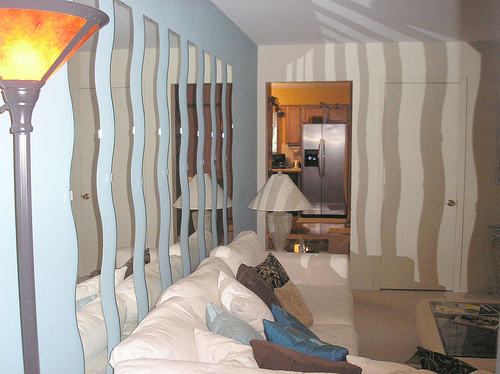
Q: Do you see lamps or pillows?
A: Yes, there is a pillow.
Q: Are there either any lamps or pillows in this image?
A: Yes, there is a pillow.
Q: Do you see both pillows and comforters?
A: No, there is a pillow but no comforters.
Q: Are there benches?
A: No, there are no benches.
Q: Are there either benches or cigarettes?
A: No, there are no benches or cigarettes.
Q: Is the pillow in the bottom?
A: Yes, the pillow is in the bottom of the image.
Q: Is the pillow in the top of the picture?
A: No, the pillow is in the bottom of the image.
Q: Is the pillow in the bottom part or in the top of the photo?
A: The pillow is in the bottom of the image.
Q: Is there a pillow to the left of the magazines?
A: Yes, there is a pillow to the left of the magazines.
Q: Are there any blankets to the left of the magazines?
A: No, there is a pillow to the left of the magazines.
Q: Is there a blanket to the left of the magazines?
A: No, there is a pillow to the left of the magazines.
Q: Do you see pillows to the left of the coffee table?
A: Yes, there is a pillow to the left of the coffee table.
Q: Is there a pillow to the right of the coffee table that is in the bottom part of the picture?
A: No, the pillow is to the left of the coffee table.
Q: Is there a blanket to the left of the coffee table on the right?
A: No, there is a pillow to the left of the coffee table.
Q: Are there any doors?
A: Yes, there is a door.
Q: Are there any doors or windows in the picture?
A: Yes, there is a door.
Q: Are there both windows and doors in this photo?
A: No, there is a door but no windows.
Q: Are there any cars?
A: No, there are no cars.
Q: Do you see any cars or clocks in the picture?
A: No, there are no cars or clocks.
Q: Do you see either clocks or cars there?
A: No, there are no cars or clocks.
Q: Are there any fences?
A: No, there are no fences.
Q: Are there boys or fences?
A: No, there are no fences or boys.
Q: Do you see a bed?
A: No, there are no beds.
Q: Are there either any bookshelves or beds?
A: No, there are no beds or bookshelves.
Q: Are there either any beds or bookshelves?
A: No, there are no beds or bookshelves.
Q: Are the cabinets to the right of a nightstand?
A: No, the cabinets are to the right of a mirror.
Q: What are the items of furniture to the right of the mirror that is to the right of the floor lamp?
A: The pieces of furniture are cabinets.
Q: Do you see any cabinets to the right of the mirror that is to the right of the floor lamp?
A: Yes, there are cabinets to the right of the mirror.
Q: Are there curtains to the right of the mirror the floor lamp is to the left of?
A: No, there are cabinets to the right of the mirror.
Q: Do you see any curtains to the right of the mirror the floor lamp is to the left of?
A: No, there are cabinets to the right of the mirror.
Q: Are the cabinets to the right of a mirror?
A: Yes, the cabinets are to the right of a mirror.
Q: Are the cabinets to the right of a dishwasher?
A: No, the cabinets are to the right of a mirror.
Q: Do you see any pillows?
A: Yes, there is a pillow.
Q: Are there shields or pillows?
A: Yes, there is a pillow.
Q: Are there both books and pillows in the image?
A: No, there is a pillow but no books.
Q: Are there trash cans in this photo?
A: No, there are no trash cans.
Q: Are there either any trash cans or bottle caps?
A: No, there are no trash cans or bottle caps.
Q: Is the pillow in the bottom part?
A: Yes, the pillow is in the bottom of the image.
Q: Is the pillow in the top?
A: No, the pillow is in the bottom of the image.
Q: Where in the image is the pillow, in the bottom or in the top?
A: The pillow is in the bottom of the image.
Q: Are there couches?
A: Yes, there is a couch.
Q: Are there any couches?
A: Yes, there is a couch.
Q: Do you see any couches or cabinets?
A: Yes, there is a couch.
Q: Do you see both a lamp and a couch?
A: Yes, there are both a couch and a lamp.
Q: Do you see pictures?
A: No, there are no pictures.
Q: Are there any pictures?
A: No, there are no pictures.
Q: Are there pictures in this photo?
A: No, there are no pictures.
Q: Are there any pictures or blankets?
A: No, there are no pictures or blankets.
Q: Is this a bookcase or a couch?
A: This is a couch.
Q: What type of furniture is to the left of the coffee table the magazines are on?
A: The piece of furniture is a couch.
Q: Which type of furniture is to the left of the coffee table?
A: The piece of furniture is a couch.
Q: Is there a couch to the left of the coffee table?
A: Yes, there is a couch to the left of the coffee table.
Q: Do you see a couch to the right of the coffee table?
A: No, the couch is to the left of the coffee table.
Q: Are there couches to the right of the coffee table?
A: No, the couch is to the left of the coffee table.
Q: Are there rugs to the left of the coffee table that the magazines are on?
A: No, there is a couch to the left of the coffee table.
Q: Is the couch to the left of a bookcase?
A: No, the couch is to the left of the coffee table.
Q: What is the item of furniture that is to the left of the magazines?
A: The piece of furniture is a couch.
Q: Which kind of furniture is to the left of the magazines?
A: The piece of furniture is a couch.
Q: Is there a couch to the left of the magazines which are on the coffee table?
A: Yes, there is a couch to the left of the magazines.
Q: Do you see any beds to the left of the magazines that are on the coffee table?
A: No, there is a couch to the left of the magazines.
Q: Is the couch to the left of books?
A: No, the couch is to the left of the magazines.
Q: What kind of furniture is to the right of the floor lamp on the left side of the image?
A: The piece of furniture is a couch.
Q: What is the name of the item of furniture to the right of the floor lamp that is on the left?
A: The piece of furniture is a couch.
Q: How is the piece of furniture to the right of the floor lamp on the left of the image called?
A: The piece of furniture is a couch.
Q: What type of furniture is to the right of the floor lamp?
A: The piece of furniture is a couch.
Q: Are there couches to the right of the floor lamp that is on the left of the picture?
A: Yes, there is a couch to the right of the floor lamp.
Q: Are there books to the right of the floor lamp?
A: No, there is a couch to the right of the floor lamp.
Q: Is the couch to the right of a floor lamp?
A: Yes, the couch is to the right of a floor lamp.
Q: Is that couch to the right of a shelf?
A: No, the couch is to the right of a floor lamp.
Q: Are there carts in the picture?
A: No, there are no carts.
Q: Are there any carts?
A: No, there are no carts.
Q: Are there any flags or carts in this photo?
A: No, there are no carts or flags.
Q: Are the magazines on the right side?
A: Yes, the magazines are on the right of the image.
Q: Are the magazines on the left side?
A: No, the magazines are on the right of the image.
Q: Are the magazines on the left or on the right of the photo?
A: The magazines are on the right of the image.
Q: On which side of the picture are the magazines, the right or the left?
A: The magazines are on the right of the image.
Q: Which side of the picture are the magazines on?
A: The magazines are on the right of the image.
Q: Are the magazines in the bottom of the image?
A: Yes, the magazines are in the bottom of the image.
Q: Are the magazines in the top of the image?
A: No, the magazines are in the bottom of the image.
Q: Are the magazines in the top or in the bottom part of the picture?
A: The magazines are in the bottom of the image.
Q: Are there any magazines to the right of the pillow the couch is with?
A: Yes, there are magazines to the right of the pillow.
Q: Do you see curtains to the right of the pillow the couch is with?
A: No, there are magazines to the right of the pillow.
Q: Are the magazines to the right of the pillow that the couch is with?
A: Yes, the magazines are to the right of the pillow.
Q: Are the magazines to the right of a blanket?
A: No, the magazines are to the right of the pillow.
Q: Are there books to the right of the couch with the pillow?
A: No, there are magazines to the right of the couch.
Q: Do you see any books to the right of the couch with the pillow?
A: No, there are magazines to the right of the couch.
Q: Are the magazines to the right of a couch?
A: Yes, the magazines are to the right of a couch.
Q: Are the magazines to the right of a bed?
A: No, the magazines are to the right of a couch.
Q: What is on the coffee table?
A: The magazines are on the coffee table.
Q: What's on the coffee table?
A: The magazines are on the coffee table.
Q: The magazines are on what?
A: The magazines are on the coffee table.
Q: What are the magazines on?
A: The magazines are on the coffee table.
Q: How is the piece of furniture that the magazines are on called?
A: The piece of furniture is a coffee table.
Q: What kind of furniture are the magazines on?
A: The magazines are on the coffee table.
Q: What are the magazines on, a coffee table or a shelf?
A: The magazines are on a coffee table.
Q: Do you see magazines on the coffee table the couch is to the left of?
A: Yes, there are magazines on the coffee table.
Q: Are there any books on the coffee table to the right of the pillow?
A: No, there are magazines on the coffee table.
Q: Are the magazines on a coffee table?
A: Yes, the magazines are on a coffee table.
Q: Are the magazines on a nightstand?
A: No, the magazines are on a coffee table.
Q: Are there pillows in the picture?
A: Yes, there is a pillow.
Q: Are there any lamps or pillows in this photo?
A: Yes, there is a pillow.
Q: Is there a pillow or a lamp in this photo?
A: Yes, there is a pillow.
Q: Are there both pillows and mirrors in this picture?
A: Yes, there are both a pillow and a mirror.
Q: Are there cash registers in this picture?
A: No, there are no cash registers.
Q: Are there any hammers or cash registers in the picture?
A: No, there are no cash registers or hammers.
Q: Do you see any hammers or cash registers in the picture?
A: No, there are no cash registers or hammers.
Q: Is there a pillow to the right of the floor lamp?
A: Yes, there is a pillow to the right of the floor lamp.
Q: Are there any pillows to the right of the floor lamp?
A: Yes, there is a pillow to the right of the floor lamp.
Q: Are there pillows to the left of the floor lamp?
A: No, the pillow is to the right of the floor lamp.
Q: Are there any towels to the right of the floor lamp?
A: No, there is a pillow to the right of the floor lamp.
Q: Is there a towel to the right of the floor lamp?
A: No, there is a pillow to the right of the floor lamp.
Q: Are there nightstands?
A: No, there are no nightstands.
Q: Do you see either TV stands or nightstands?
A: No, there are no nightstands or TV stands.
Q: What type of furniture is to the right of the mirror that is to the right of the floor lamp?
A: The piece of furniture is an end table.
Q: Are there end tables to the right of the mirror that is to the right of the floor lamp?
A: Yes, there is an end table to the right of the mirror.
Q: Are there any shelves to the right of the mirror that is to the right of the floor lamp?
A: No, there is an end table to the right of the mirror.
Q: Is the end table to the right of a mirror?
A: Yes, the end table is to the right of a mirror.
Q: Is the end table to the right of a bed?
A: No, the end table is to the right of a mirror.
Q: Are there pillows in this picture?
A: Yes, there are pillows.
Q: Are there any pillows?
A: Yes, there are pillows.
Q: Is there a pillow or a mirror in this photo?
A: Yes, there are pillows.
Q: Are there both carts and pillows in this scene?
A: No, there are pillows but no carts.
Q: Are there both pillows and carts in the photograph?
A: No, there are pillows but no carts.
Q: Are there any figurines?
A: No, there are no figurines.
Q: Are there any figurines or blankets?
A: No, there are no figurines or blankets.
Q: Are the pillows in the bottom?
A: Yes, the pillows are in the bottom of the image.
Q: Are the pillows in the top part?
A: No, the pillows are in the bottom of the image.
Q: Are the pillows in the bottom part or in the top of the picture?
A: The pillows are in the bottom of the image.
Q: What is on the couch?
A: The pillows are on the couch.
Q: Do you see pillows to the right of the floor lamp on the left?
A: Yes, there are pillows to the right of the floor lamp.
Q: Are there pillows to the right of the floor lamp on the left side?
A: Yes, there are pillows to the right of the floor lamp.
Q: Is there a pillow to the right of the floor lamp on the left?
A: Yes, there are pillows to the right of the floor lamp.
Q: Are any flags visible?
A: No, there are no flags.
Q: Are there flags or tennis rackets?
A: No, there are no flags or tennis rackets.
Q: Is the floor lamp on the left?
A: Yes, the floor lamp is on the left of the image.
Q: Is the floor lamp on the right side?
A: No, the floor lamp is on the left of the image.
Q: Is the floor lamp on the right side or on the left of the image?
A: The floor lamp is on the left of the image.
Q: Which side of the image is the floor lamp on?
A: The floor lamp is on the left of the image.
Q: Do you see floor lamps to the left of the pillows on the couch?
A: Yes, there is a floor lamp to the left of the pillows.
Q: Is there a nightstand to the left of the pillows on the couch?
A: No, there is a floor lamp to the left of the pillows.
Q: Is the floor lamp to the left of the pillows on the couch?
A: Yes, the floor lamp is to the left of the pillows.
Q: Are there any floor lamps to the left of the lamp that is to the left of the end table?
A: Yes, there is a floor lamp to the left of the lamp.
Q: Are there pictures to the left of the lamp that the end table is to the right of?
A: No, there is a floor lamp to the left of the lamp.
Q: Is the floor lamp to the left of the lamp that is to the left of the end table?
A: Yes, the floor lamp is to the left of the lamp.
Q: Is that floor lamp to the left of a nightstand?
A: No, the floor lamp is to the left of the lamp.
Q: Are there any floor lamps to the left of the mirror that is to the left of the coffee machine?
A: Yes, there is a floor lamp to the left of the mirror.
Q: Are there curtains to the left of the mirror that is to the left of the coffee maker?
A: No, there is a floor lamp to the left of the mirror.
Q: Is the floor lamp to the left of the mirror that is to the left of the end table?
A: Yes, the floor lamp is to the left of the mirror.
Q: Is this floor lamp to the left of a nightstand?
A: No, the floor lamp is to the left of the mirror.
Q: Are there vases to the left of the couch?
A: No, there is a floor lamp to the left of the couch.